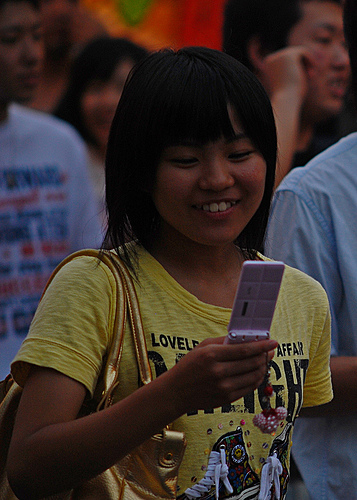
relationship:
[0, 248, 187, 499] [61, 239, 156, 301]
handbag hanging under shoulder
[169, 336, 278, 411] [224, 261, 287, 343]
hand holding phone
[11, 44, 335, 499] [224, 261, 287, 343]
girl using phone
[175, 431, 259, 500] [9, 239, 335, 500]
shoe printed on shirt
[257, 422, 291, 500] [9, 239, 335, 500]
shoe printed on shirt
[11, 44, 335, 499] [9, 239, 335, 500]
girl wearing shirt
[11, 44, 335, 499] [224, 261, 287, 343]
girl smiling at phone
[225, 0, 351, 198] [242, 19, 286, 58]
man talking on phone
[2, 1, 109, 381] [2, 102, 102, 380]
man wearing shirt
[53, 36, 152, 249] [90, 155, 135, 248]
woman wearing shirt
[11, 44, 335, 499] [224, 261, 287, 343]
girl holding phone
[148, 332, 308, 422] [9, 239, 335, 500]
words printed on shirt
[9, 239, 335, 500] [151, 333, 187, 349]
shirt says love